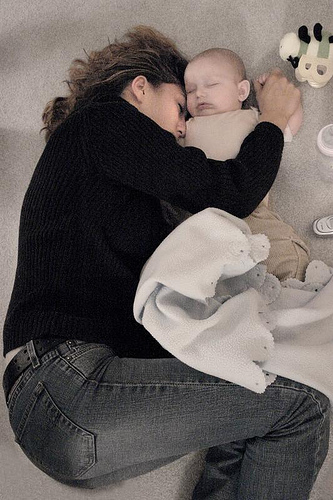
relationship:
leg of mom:
[88, 347, 321, 499] [0, 23, 333, 500]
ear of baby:
[237, 78, 252, 104] [166, 41, 309, 324]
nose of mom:
[176, 111, 191, 136] [0, 23, 333, 500]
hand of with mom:
[251, 66, 302, 119] [0, 23, 333, 500]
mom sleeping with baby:
[0, 23, 330, 498] [161, 46, 310, 287]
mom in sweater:
[0, 23, 333, 500] [2, 89, 285, 357]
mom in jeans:
[0, 23, 333, 500] [11, 336, 322, 497]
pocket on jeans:
[7, 398, 86, 483] [11, 336, 322, 497]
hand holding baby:
[251, 71, 299, 126] [178, 46, 305, 329]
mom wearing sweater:
[0, 23, 333, 500] [4, 99, 282, 354]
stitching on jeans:
[97, 376, 214, 390] [12, 331, 314, 484]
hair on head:
[39, 23, 189, 144] [56, 25, 197, 146]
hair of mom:
[39, 23, 189, 144] [0, 23, 333, 500]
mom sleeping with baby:
[0, 23, 333, 500] [177, 47, 309, 283]